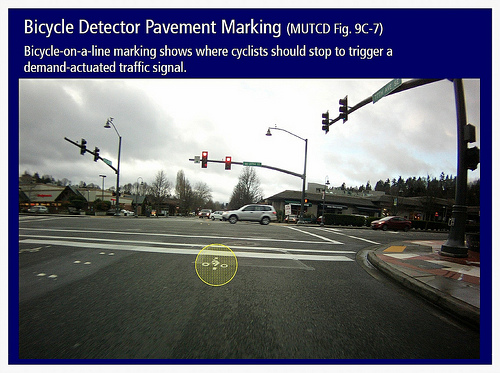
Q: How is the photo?
A: Clear.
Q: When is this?
A: Daytime.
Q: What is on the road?
A: White lines.